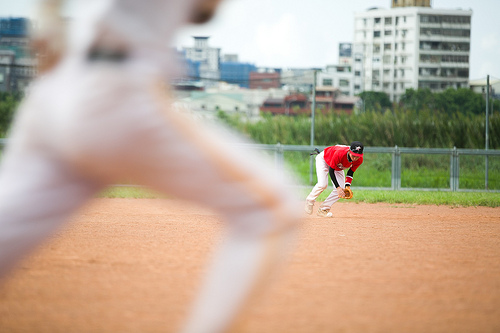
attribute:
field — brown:
[0, 195, 500, 326]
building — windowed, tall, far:
[350, 8, 479, 110]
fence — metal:
[229, 140, 497, 192]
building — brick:
[259, 83, 359, 122]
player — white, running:
[4, 4, 311, 332]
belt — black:
[70, 43, 138, 69]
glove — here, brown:
[337, 184, 359, 201]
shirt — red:
[324, 142, 363, 172]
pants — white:
[312, 151, 347, 216]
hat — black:
[349, 139, 365, 156]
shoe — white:
[315, 205, 336, 221]